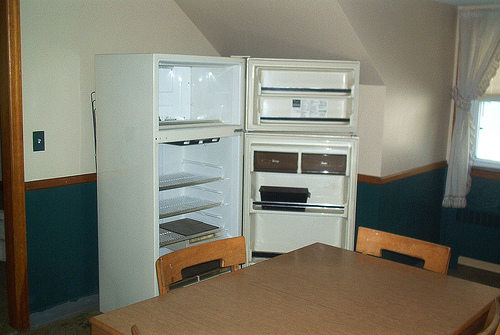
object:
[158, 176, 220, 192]
metal shelves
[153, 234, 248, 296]
chair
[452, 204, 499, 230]
heating vents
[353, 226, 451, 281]
chair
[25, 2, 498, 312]
walls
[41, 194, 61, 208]
blue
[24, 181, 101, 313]
wainscoting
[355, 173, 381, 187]
wooden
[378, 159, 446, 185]
border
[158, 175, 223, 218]
empty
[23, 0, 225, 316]
wall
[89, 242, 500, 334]
table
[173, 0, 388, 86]
ceiling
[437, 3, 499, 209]
curtain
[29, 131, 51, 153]
switch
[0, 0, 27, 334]
doorway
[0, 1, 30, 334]
door frame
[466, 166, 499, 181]
wood grain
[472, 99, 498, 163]
kitchen window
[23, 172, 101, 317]
green wall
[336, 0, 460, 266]
wall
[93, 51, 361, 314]
fridge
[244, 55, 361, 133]
door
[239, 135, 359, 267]
door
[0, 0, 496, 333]
kitchen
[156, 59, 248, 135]
freezer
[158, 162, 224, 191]
shelf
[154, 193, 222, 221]
shelf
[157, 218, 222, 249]
shelf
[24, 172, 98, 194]
rail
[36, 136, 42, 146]
light switch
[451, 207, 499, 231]
vent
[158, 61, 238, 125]
inside